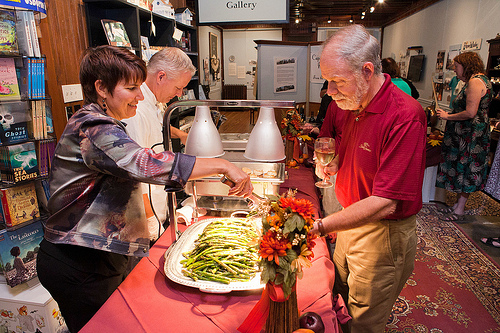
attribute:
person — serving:
[34, 42, 252, 332]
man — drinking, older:
[307, 20, 430, 332]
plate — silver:
[162, 205, 266, 298]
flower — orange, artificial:
[259, 232, 290, 264]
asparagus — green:
[190, 266, 231, 284]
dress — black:
[435, 73, 493, 198]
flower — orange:
[284, 193, 315, 220]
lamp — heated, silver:
[239, 105, 289, 164]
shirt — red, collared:
[334, 72, 429, 222]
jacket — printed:
[39, 103, 198, 260]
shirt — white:
[122, 83, 169, 227]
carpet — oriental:
[382, 205, 500, 332]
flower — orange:
[303, 230, 317, 263]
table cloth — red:
[78, 166, 351, 332]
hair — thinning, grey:
[318, 23, 386, 75]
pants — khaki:
[331, 215, 418, 332]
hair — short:
[78, 43, 147, 105]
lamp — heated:
[183, 103, 228, 159]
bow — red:
[236, 276, 299, 332]